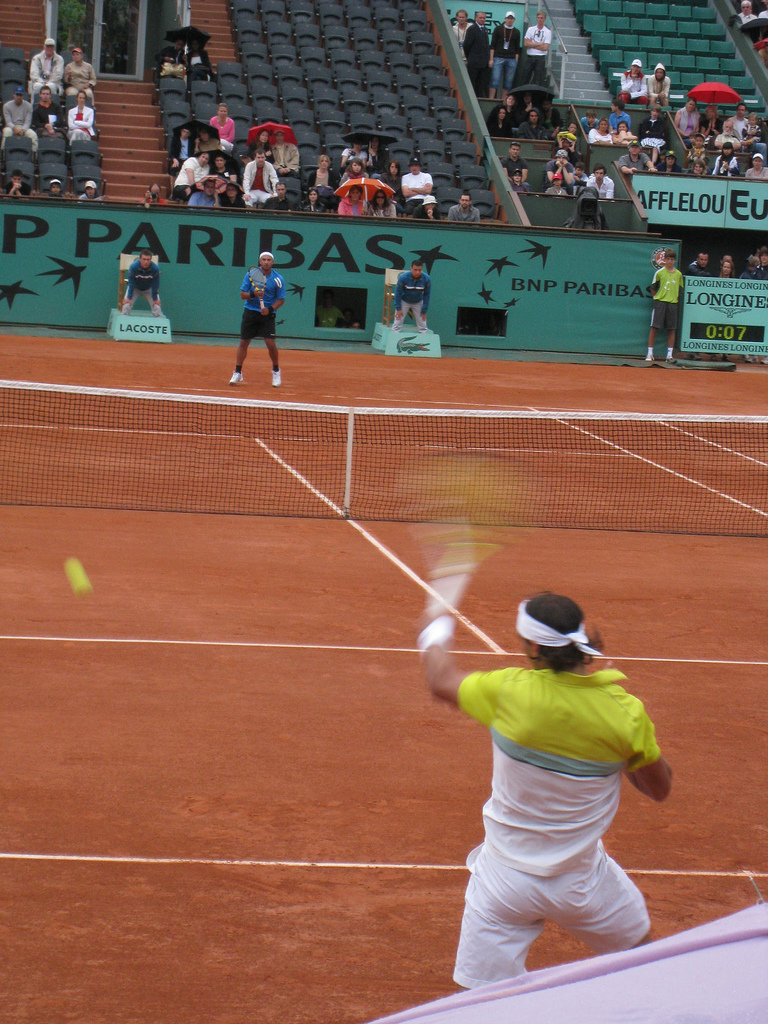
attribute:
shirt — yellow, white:
[450, 659, 659, 879]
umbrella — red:
[682, 75, 744, 130]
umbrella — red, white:
[327, 174, 398, 206]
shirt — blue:
[239, 268, 286, 315]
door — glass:
[47, 0, 188, 83]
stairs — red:
[87, 71, 176, 202]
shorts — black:
[241, 308, 285, 341]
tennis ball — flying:
[54, 545, 107, 603]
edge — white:
[197, 386, 361, 425]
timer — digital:
[702, 321, 752, 346]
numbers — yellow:
[699, 321, 749, 340]